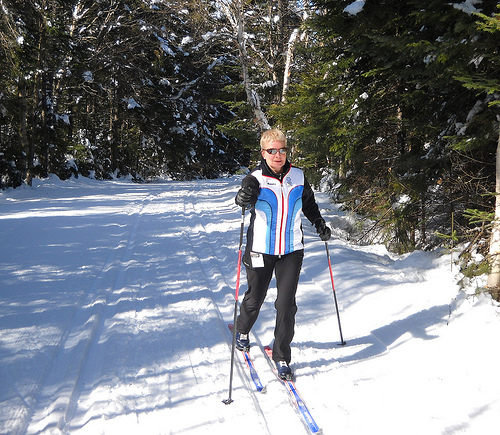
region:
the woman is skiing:
[144, 83, 381, 418]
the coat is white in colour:
[243, 153, 320, 278]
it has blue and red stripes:
[233, 156, 322, 266]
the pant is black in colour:
[176, 226, 308, 378]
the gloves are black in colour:
[234, 188, 259, 206]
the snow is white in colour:
[125, 178, 171, 355]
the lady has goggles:
[241, 138, 295, 160]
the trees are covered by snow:
[304, 4, 441, 81]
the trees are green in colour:
[313, 72, 406, 164]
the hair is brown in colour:
[259, 125, 287, 145]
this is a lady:
[223, 121, 319, 351]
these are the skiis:
[218, 330, 317, 386]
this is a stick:
[220, 256, 257, 318]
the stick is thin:
[203, 245, 252, 320]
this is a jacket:
[254, 186, 299, 245]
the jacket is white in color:
[255, 181, 301, 249]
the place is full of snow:
[98, 274, 210, 367]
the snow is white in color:
[69, 263, 198, 398]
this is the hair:
[265, 128, 282, 138]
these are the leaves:
[378, 135, 480, 210]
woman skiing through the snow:
[217, 135, 331, 434]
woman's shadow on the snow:
[292, 284, 464, 381]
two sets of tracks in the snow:
[22, 163, 309, 430]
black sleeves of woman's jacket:
[237, 174, 331, 231]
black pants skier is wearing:
[237, 253, 303, 361]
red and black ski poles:
[220, 203, 348, 389]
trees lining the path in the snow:
[6, 4, 499, 247]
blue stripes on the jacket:
[254, 187, 302, 255]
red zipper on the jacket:
[277, 183, 289, 255]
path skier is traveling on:
[10, 180, 438, 431]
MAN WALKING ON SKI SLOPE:
[232, 109, 319, 376]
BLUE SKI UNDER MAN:
[282, 300, 369, 427]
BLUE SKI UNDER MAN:
[211, 281, 257, 402]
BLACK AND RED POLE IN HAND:
[295, 213, 338, 306]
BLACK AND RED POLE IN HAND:
[225, 218, 246, 430]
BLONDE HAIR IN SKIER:
[261, 114, 291, 159]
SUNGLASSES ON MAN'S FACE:
[257, 131, 290, 151]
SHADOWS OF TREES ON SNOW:
[84, 225, 226, 359]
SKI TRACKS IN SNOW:
[87, 204, 205, 337]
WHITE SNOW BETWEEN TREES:
[150, 252, 237, 401]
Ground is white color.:
[35, 209, 310, 413]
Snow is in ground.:
[58, 223, 294, 404]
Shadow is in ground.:
[18, 190, 298, 378]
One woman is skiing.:
[215, 120, 320, 400]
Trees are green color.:
[25, 20, 432, 155]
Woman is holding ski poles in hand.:
[215, 118, 355, 412]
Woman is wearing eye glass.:
[242, 133, 304, 172]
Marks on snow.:
[39, 260, 309, 422]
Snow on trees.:
[58, 10, 244, 168]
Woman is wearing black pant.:
[227, 127, 308, 382]